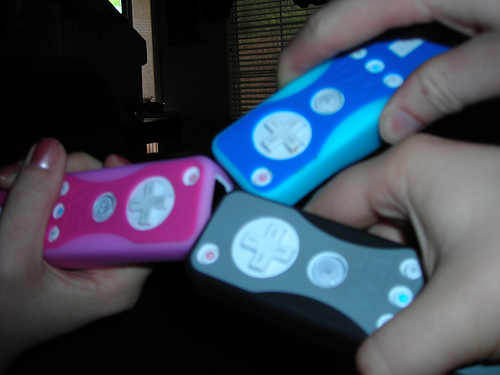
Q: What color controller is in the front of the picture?
A: Grey.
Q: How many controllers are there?
A: 3.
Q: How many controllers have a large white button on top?
A: 3.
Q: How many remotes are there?
A: 3.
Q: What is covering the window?
A: Blinds.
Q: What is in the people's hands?
A: Wii remotes.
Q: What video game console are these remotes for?
A: Wii.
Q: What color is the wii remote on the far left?
A: Pink.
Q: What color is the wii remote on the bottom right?
A: Black and gray.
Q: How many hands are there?
A: 3.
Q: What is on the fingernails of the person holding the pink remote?
A: Nail polish.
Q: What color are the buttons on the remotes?
A: White.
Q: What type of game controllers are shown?
A: WII.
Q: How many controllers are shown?
A: 3.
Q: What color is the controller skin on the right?
A: Pink.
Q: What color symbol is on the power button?
A: Red.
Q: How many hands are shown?
A: 3.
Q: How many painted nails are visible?
A: 3.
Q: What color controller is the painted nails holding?
A: Pink.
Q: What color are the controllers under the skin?
A: White.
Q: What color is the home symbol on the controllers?
A: Green.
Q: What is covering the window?
A: Blinds.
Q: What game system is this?
A: Wii.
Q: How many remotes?
A: Three.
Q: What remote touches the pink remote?
A: All of them.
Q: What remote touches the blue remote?
A: Pink and grey.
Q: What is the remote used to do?
A: Play games.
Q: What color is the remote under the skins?
A: White.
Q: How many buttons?
A: Six.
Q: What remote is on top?
A: Blue.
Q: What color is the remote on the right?
A: Black.